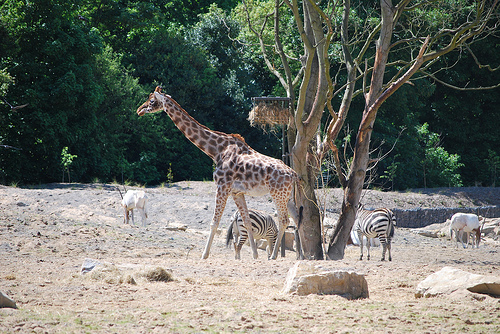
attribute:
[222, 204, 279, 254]
zebra — white, black, striped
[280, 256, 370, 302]
rock — large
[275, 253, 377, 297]
rock — LARGE, LIGHT BROWN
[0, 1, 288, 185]
green trees — dense, bushy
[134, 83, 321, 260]
giraffe — tall, brown, white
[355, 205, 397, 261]
zebra — black, white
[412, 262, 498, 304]
rock — large, light brown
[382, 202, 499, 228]
barrier — stone, grey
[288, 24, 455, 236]
tree — large, leafless